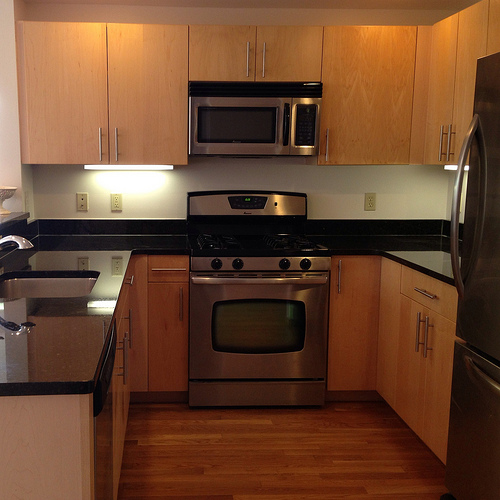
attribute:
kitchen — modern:
[0, 0, 499, 499]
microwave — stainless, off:
[185, 82, 323, 158]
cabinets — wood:
[181, 27, 323, 87]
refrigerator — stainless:
[435, 56, 500, 357]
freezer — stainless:
[448, 343, 497, 499]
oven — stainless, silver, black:
[183, 190, 333, 411]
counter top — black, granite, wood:
[2, 221, 464, 400]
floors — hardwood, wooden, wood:
[124, 401, 442, 499]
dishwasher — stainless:
[93, 326, 127, 499]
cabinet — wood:
[314, 23, 420, 169]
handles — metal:
[320, 132, 335, 164]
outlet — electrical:
[111, 193, 124, 216]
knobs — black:
[202, 256, 323, 274]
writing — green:
[239, 195, 256, 203]